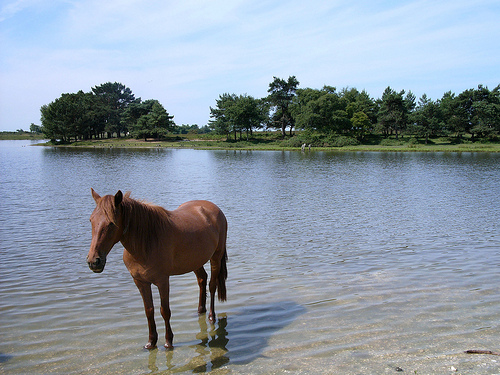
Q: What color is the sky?
A: Blue.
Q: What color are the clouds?
A: White.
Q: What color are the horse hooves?
A: Brown.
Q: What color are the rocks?
A: Gray.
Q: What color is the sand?
A: Gray.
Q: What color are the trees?
A: Green.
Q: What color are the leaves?
A: Green.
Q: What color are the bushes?
A: Green.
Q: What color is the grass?
A: Green.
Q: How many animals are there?
A: One.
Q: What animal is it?
A: Horse.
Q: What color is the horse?
A: Brown.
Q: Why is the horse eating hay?
A: It isn't.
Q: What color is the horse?
A: Brown.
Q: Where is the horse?
A: In the water.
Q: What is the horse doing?
A: Standing still.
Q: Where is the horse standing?
A: In a lake.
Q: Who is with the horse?
A: Noone.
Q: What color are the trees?
A: Green.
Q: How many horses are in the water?
A: One.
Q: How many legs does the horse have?
A: 4.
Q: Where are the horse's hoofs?
A: In the water.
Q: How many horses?
A: 1.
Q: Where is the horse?
A: In the water.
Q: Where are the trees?
A: Across the water.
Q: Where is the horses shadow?
A: To its left.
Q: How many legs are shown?
A: 4.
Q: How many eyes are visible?
A: 1.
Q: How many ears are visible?
A: 2.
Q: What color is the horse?
A: Brown.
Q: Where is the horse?
A: In the water.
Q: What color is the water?
A: Blue.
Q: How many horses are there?
A: One.